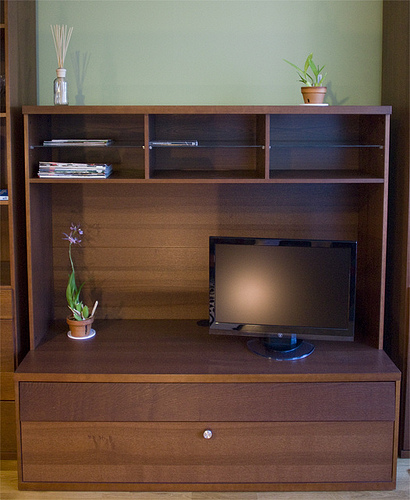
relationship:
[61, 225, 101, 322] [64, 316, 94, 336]
flower in a pot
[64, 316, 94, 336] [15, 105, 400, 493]
pot on a desk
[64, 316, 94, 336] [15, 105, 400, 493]
pot on top of desk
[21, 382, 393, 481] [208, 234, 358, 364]
drawer under monitor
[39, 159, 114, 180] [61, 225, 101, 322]
magazines above a flower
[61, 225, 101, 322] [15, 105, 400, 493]
flower on a desk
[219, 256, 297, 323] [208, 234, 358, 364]
light shining on a monitor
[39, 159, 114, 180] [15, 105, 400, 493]
magazines on a desk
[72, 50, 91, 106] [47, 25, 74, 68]
shadows behind sticks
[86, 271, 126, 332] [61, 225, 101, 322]
shadow of a flower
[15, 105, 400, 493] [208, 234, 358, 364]
desk with a monitor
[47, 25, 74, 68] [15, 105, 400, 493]
sticks on top of desk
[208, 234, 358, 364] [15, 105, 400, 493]
monitor on a desk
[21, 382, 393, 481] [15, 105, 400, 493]
drawer on a desk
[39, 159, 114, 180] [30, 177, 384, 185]
magazines on a shelf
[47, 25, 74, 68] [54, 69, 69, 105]
sticks in a bottle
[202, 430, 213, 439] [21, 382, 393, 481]
knob on a drawer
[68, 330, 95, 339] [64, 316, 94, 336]
plate under pot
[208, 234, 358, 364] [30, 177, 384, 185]
monitor under shelf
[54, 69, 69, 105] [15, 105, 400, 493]
bottle on a desk